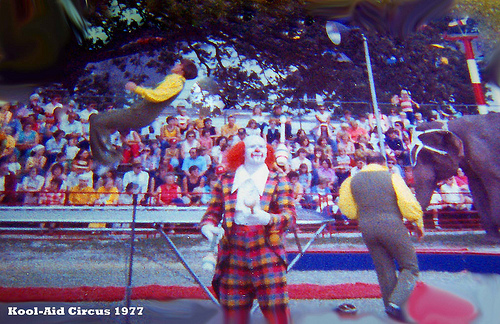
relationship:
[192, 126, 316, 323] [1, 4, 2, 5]
clown in circus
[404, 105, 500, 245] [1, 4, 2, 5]
elephant in circus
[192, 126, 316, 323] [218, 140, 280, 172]
clown has red hair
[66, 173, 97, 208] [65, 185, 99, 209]
person wears yellow jacket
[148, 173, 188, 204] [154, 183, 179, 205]
woman wears red top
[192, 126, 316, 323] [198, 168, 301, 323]
clown wears squared cloths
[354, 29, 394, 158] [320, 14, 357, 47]
pole of light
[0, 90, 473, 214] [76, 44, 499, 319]
people watching show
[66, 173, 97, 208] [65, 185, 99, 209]
man wearing yellow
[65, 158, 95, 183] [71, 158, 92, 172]
man wears hat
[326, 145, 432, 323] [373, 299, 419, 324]
man wears shoe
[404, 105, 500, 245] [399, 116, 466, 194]
elephant something on head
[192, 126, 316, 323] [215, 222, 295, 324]
clown with pants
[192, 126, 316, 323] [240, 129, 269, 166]
person face painted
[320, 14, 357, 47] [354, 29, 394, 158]
light on pole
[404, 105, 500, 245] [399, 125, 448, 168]
elephant wearing decoration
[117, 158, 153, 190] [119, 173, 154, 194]
person with white shirt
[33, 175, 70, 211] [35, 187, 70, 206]
person with shirt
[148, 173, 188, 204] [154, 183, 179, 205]
person with tank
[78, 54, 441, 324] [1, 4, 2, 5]
entertainers at circus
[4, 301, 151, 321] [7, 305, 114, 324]
letters says kool-aid circus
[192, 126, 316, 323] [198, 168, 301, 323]
clown wears plaid outfi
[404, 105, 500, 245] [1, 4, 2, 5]
elephant at circus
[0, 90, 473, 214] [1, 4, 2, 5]
crowd watches circus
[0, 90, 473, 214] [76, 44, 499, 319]
spectators watch show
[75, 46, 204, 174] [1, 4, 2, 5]
acrobat at circus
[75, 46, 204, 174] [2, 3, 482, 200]
man in air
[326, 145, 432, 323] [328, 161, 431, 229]
man has yellow shirt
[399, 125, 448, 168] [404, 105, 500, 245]
clothe on elephant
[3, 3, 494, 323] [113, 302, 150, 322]
picture taken in 1977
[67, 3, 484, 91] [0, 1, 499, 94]
trees in background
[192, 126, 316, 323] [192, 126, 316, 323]
person dressed as a clown